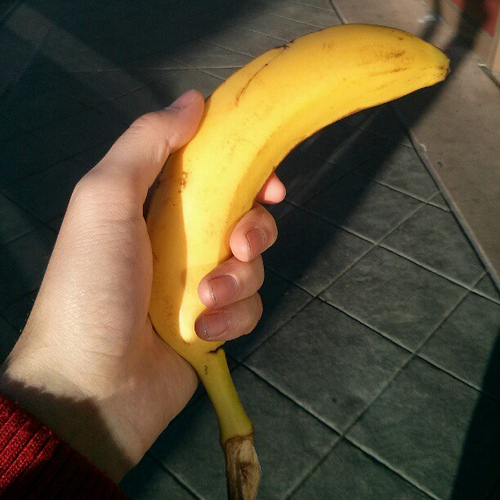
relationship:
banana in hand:
[180, 24, 450, 222] [6, 96, 285, 346]